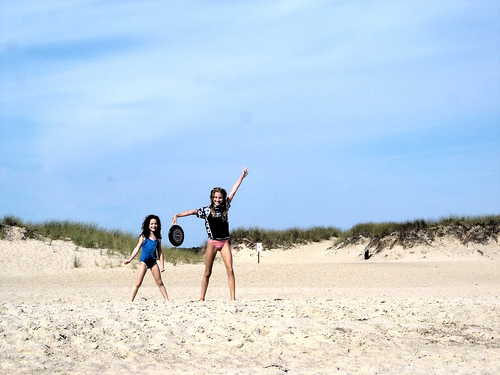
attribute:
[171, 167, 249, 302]
girl — bigger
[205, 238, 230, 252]
bottom — pink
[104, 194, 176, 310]
girl — younger